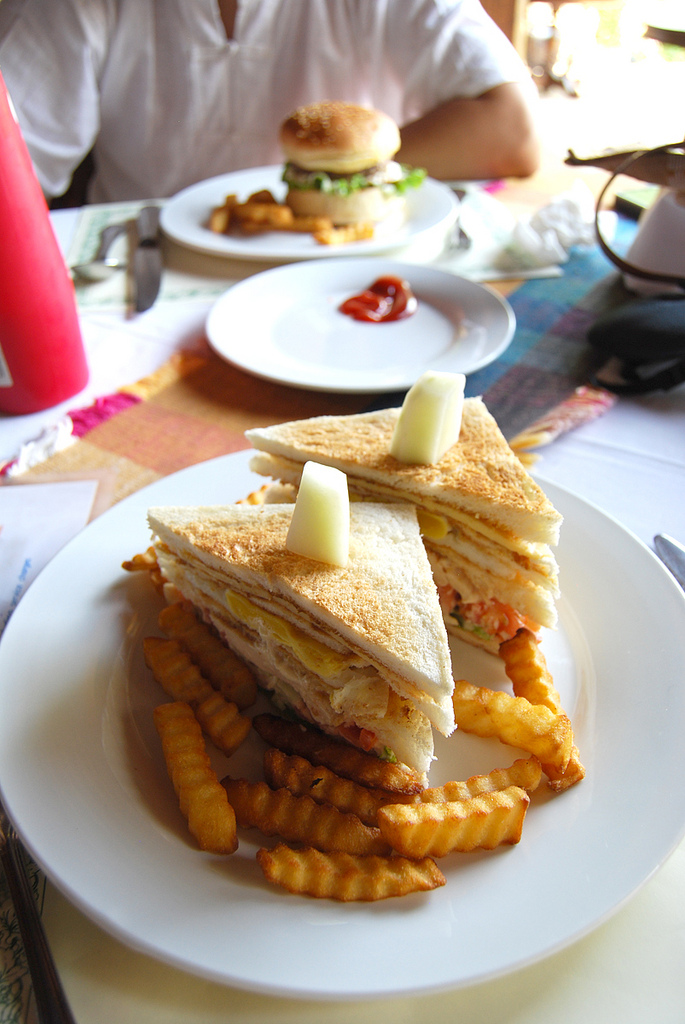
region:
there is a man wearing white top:
[186, 35, 460, 98]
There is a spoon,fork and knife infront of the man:
[86, 197, 545, 299]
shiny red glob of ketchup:
[339, 272, 420, 327]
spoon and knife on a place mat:
[75, 205, 163, 313]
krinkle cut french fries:
[193, 755, 507, 885]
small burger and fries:
[144, 115, 443, 238]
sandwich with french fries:
[71, 422, 616, 888]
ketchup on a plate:
[238, 277, 502, 376]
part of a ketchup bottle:
[1, 97, 98, 440]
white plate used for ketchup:
[172, 252, 561, 418]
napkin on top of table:
[451, 181, 611, 289]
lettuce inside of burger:
[275, 161, 432, 216]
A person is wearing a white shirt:
[43, 7, 491, 224]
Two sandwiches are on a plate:
[148, 367, 556, 768]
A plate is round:
[20, 423, 654, 1020]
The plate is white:
[35, 465, 649, 985]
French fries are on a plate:
[120, 640, 517, 906]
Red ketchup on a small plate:
[296, 253, 468, 374]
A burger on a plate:
[250, 71, 432, 248]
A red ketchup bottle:
[0, 62, 135, 436]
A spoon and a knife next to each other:
[75, 205, 198, 345]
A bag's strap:
[578, 119, 681, 347]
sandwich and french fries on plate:
[78, 371, 652, 911]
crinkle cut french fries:
[194, 720, 441, 904]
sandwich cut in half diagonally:
[150, 377, 594, 759]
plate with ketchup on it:
[230, 241, 520, 393]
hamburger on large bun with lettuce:
[272, 79, 434, 246]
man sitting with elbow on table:
[383, 0, 571, 188]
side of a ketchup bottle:
[0, 82, 101, 401]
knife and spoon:
[72, 164, 175, 319]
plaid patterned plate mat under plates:
[496, 196, 667, 453]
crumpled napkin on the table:
[484, 155, 634, 280]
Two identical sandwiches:
[139, 373, 589, 764]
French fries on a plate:
[130, 688, 580, 952]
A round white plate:
[30, 447, 653, 980]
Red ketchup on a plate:
[298, 241, 466, 372]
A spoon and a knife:
[60, 200, 190, 337]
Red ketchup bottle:
[2, 72, 101, 446]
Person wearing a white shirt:
[60, 2, 433, 222]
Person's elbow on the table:
[383, 60, 577, 212]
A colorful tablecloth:
[82, 283, 646, 491]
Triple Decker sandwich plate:
[228, 392, 560, 678]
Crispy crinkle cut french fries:
[132, 651, 572, 907]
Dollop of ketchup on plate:
[322, 262, 445, 335]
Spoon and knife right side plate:
[77, 202, 169, 313]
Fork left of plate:
[440, 178, 483, 258]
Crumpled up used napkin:
[499, 189, 596, 289]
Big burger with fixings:
[280, 85, 398, 214]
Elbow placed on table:
[403, 58, 556, 189]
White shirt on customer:
[52, 6, 513, 124]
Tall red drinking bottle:
[4, 86, 96, 427]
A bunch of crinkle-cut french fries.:
[150, 743, 582, 923]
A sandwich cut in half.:
[152, 368, 583, 779]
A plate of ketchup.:
[293, 270, 451, 337]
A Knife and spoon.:
[82, 197, 168, 310]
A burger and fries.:
[167, 93, 492, 252]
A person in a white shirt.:
[46, 18, 534, 197]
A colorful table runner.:
[50, 270, 576, 469]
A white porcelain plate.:
[11, 678, 130, 937]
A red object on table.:
[1, 66, 109, 430]